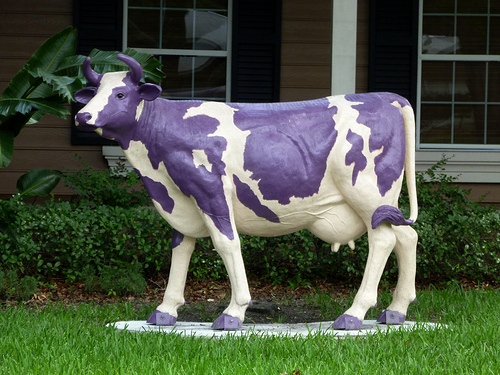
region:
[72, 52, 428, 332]
a cow statue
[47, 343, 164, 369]
green grass on the ground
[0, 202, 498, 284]
bushes behind cow statue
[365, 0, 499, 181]
a window with shutters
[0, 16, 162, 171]
large plant leaves behind cow statue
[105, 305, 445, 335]
a concrete platform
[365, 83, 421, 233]
tail of cow statue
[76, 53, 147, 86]
horns of cow statue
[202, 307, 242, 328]
hoof of cow statue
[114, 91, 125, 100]
eye of cow statue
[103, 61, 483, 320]
cow is black and white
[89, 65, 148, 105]
cow has black horns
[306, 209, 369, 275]
cow has white udders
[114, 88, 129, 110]
cow has black eyes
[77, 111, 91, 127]
cow has black nose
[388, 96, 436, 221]
cow has white tail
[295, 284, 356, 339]
cow has black hooves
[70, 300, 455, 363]
white platform is on grass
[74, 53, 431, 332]
cow is plaster-based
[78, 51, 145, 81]
Horns on a cow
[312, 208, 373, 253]
Udder under a cow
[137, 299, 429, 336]
Four hooves of a cow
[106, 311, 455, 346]
White platform under a cow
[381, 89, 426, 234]
Black and white cow tail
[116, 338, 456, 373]
Green grass under a cow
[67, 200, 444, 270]
Bushes behind a cow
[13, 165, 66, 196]
Green leaf on a plant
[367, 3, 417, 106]
Black shutters on a window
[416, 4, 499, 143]
Window on a house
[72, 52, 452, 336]
garden statue of cow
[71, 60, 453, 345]
cow statue has horns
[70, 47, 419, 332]
cow is white and blue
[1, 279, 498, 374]
grass is long and green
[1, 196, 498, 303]
hedge on top of wood chips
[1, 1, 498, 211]
brown siding on house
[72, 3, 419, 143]
green window shutter sets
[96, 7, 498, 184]
window trim is white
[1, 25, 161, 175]
large green leaves on plant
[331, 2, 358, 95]
white banister pole behind cow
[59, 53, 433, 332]
The cow is purple and white.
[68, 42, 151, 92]
The cow has horns.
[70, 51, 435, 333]
A cow statue.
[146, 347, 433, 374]
The grass is green.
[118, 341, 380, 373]
The grass is long.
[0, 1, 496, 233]
A building is behind the cow.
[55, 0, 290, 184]
Windows are in the building.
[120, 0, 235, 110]
The windows are white.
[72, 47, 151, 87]
The horns are purple.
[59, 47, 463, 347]
A purple and white statue.